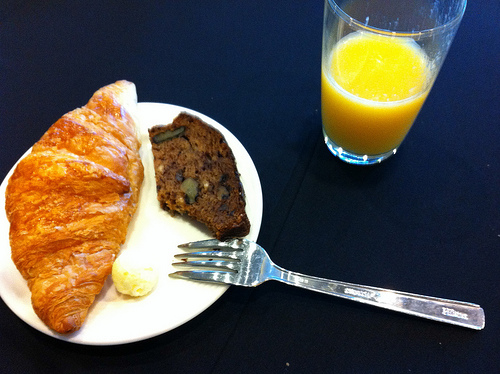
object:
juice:
[316, 27, 430, 152]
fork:
[167, 236, 485, 334]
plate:
[0, 102, 263, 346]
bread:
[6, 79, 144, 337]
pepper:
[149, 129, 189, 141]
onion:
[180, 177, 200, 205]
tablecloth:
[0, 2, 498, 373]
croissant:
[98, 71, 143, 126]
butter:
[110, 246, 158, 298]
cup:
[318, 1, 467, 166]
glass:
[327, 134, 426, 168]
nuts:
[98, 191, 122, 204]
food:
[146, 108, 251, 241]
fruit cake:
[221, 216, 245, 226]